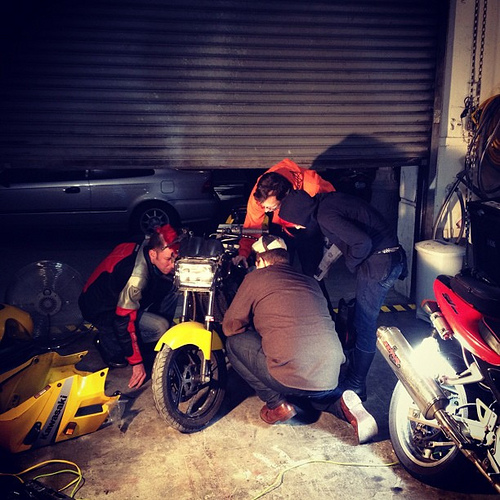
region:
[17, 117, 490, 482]
Men looking at a motorcycle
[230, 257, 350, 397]
A long sleeve brown shirt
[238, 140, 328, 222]
An orange hooded jacket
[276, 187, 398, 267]
A black hooded jacket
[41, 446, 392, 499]
A yellow cord on floor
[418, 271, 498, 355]
A red seat on motorcycle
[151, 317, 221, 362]
A yellow fender on front of motorcycle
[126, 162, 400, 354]
Four men working on a motorcyle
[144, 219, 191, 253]
A man with a red mohawk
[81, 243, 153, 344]
A red, black and silver jacket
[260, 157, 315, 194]
red jacket on person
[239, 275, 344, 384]
grey t shirt on person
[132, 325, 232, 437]
black wheel on motorcycle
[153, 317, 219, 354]
yellow frame to motorcycle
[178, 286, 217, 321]
black shocks on cycle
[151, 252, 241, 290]
silver top of cycle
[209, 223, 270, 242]
black handle bars of motorcycle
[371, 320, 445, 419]
silver muffler of motocycle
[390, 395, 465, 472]
black wheel of motorcycle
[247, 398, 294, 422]
brown shoe on foot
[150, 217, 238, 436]
a yellow motorcycle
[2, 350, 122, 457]
a part from the yellow motorcyle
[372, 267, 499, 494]
the back of a red motorcycle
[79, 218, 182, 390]
a man looking at the yellow motorcycle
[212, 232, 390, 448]
a man looking at the yellow motorcycle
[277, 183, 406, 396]
a man looking at the yellow motorcycle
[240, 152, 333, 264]
a man looking at the yellow motorcycle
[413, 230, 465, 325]
a trash can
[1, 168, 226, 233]
a car in the background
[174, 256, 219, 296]
the headlight on the motorcyle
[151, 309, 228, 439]
the front wheel of a motorbike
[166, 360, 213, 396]
the spoke of a motorbike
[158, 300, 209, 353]
the wheel guard of a wheel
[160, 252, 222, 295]
the light of a motorbike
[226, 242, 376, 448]
a man sitting on the ground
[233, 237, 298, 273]
the head of a man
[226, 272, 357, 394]
the brown shirt of a man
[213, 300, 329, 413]
the pants of a man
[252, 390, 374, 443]
the shoes of a man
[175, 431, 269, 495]
the floor of a garage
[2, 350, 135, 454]
Yellow part to a motorcycle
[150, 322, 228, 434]
Yellow tire fender on a motorcycle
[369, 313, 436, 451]
Silver muffler on a motorcycle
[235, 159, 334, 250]
Man bent over wearing an orange jacket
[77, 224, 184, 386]
Man wearing black, red and silver jacket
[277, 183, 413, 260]
Person wearing a blue hooded jacket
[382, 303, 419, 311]
Black and yellow stripes on the floor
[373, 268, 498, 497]
Rear end of a red motorcycle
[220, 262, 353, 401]
Kneeling man is wearing brown shirt